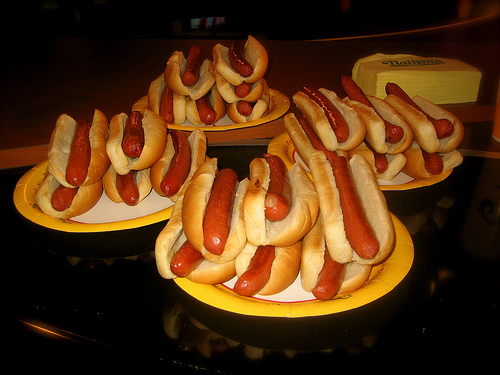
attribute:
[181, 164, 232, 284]
hot dogs — plain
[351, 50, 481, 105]
napkin stack — white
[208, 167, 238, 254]
hot dogs — red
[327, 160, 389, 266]
dog — brown 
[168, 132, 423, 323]
plate — large 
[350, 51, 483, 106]
butter — yellow 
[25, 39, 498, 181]
wood surface — brown 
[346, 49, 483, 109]
napkins — stack 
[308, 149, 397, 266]
hotdog — cooked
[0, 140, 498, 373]
surface — black 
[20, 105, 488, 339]
table — black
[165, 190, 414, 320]
plate — yellow